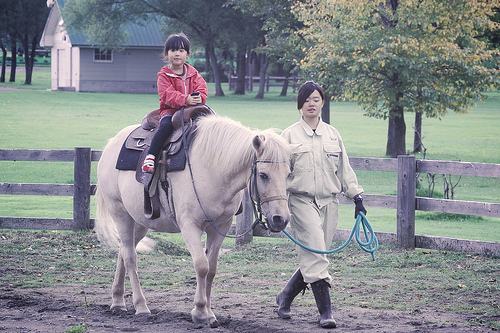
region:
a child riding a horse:
[87, 33, 293, 250]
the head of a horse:
[246, 126, 303, 234]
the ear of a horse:
[247, 131, 266, 161]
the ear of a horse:
[288, 138, 309, 159]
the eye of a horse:
[254, 163, 274, 184]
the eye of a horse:
[286, 168, 294, 185]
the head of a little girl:
[159, 28, 199, 71]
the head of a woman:
[292, 72, 326, 120]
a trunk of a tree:
[383, 95, 408, 160]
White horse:
[94, 114, 301, 326]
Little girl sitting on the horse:
[141, 31, 208, 176]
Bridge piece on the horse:
[115, 104, 210, 174]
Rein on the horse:
[178, 105, 290, 238]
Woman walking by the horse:
[263, 79, 367, 328]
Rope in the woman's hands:
[283, 211, 379, 261]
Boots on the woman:
[275, 269, 336, 328]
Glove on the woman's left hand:
[352, 195, 368, 220]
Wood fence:
[3, 147, 499, 256]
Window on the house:
[91, 47, 114, 62]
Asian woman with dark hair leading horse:
[268, 78, 373, 327]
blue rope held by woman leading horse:
[268, 205, 385, 264]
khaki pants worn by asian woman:
[285, 193, 347, 285]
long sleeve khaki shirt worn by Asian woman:
[253, 114, 363, 208]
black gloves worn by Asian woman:
[354, 193, 370, 220]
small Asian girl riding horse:
[137, 28, 219, 180]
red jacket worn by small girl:
[150, 59, 215, 121]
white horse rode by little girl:
[84, 108, 296, 326]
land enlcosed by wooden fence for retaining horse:
[2, 143, 499, 329]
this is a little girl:
[123, 22, 225, 178]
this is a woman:
[254, 58, 368, 328]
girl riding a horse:
[57, 4, 334, 329]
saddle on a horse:
[110, 94, 207, 159]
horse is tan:
[73, 100, 328, 330]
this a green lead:
[232, 159, 397, 267]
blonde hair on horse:
[176, 110, 271, 173]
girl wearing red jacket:
[140, 52, 206, 108]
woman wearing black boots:
[275, 250, 350, 330]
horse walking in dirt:
[103, 39, 313, 324]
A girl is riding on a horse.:
[85, 26, 296, 332]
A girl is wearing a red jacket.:
[152, 62, 209, 124]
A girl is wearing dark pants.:
[144, 113, 178, 162]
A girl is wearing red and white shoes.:
[138, 152, 156, 177]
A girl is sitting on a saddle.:
[114, 32, 216, 219]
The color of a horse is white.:
[85, 99, 297, 331]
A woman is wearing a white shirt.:
[274, 113, 365, 206]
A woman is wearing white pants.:
[275, 184, 342, 288]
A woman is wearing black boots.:
[274, 265, 341, 331]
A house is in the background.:
[37, 2, 206, 98]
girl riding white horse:
[85, 26, 302, 323]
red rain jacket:
[147, 64, 220, 119]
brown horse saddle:
[126, 100, 204, 212]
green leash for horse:
[246, 188, 406, 273]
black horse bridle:
[241, 165, 263, 240]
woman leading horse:
[265, 73, 372, 330]